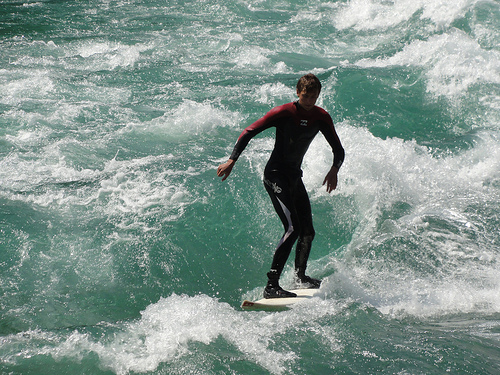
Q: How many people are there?
A: One.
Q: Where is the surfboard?
A: Under the man.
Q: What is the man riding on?
A: A surfboard.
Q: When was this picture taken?
A: During the day.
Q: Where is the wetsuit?
A: On the man.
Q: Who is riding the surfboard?
A: A man in a wet suit.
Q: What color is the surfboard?
A: White.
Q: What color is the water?
A: Blue.